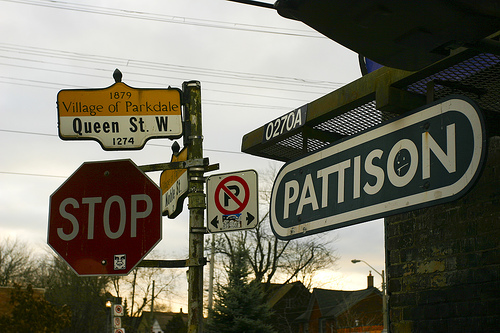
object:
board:
[44, 157, 164, 278]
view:
[4, 2, 498, 326]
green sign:
[270, 95, 488, 242]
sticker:
[110, 252, 129, 270]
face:
[107, 250, 128, 270]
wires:
[1, 0, 349, 195]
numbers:
[261, 110, 293, 145]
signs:
[45, 66, 261, 280]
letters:
[275, 120, 466, 222]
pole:
[188, 77, 204, 331]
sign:
[56, 70, 187, 156]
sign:
[204, 167, 259, 231]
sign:
[45, 157, 162, 278]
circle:
[215, 176, 249, 214]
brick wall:
[381, 71, 498, 328]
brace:
[138, 258, 208, 268]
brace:
[138, 156, 211, 171]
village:
[0, 214, 485, 329]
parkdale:
[119, 95, 178, 114]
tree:
[203, 228, 323, 330]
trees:
[196, 235, 346, 332]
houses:
[256, 266, 383, 328]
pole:
[361, 261, 389, 331]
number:
[263, 106, 292, 139]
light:
[347, 257, 368, 265]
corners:
[452, 148, 484, 198]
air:
[0, 1, 499, 332]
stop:
[52, 190, 152, 239]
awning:
[242, 77, 371, 140]